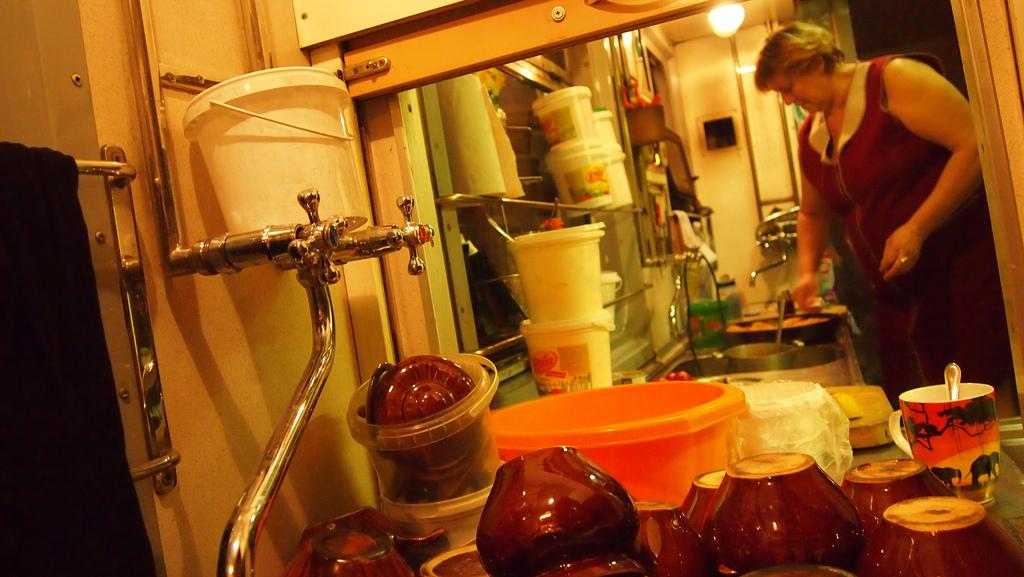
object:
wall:
[0, 1, 399, 526]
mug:
[882, 375, 1005, 512]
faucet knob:
[273, 192, 438, 278]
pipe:
[202, 270, 345, 575]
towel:
[5, 132, 177, 569]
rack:
[67, 144, 183, 496]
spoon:
[939, 360, 963, 401]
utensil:
[774, 290, 790, 354]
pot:
[722, 339, 804, 374]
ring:
[895, 256, 910, 267]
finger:
[882, 249, 909, 281]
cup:
[471, 443, 646, 577]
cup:
[693, 448, 872, 576]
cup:
[850, 492, 1021, 576]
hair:
[748, 21, 846, 96]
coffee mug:
[894, 377, 1005, 505]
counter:
[291, 302, 1023, 575]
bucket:
[180, 63, 371, 239]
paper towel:
[434, 72, 509, 201]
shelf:
[431, 191, 646, 216]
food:
[724, 316, 829, 333]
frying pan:
[714, 310, 849, 352]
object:
[513, 310, 616, 400]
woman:
[756, 22, 1011, 429]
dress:
[790, 53, 1022, 421]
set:
[488, 130, 625, 403]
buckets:
[505, 218, 611, 325]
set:
[205, 156, 381, 295]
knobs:
[191, 187, 360, 287]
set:
[158, 158, 571, 347]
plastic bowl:
[479, 378, 752, 511]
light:
[699, 0, 753, 41]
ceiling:
[645, 0, 845, 46]